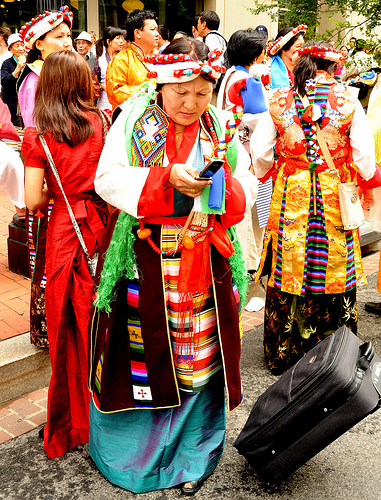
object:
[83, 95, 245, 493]
costume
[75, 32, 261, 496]
woman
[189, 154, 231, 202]
phone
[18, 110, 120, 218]
shirt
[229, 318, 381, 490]
suitcase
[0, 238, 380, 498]
floor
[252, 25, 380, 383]
women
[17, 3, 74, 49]
headdress